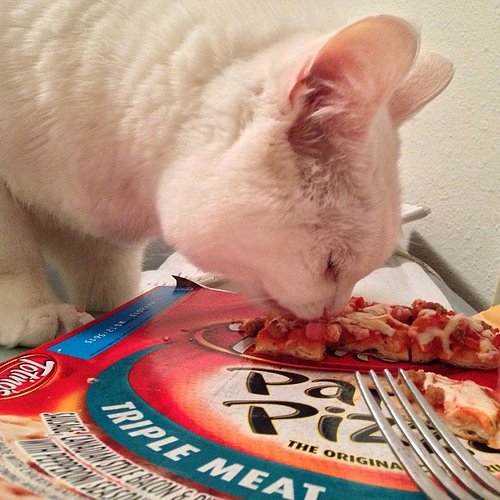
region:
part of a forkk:
[401, 400, 441, 447]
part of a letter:
[233, 398, 267, 450]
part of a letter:
[173, 425, 203, 471]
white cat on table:
[0, 0, 456, 347]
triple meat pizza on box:
[240, 297, 499, 450]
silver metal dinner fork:
[353, 364, 498, 499]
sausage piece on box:
[240, 315, 263, 335]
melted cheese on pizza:
[353, 305, 391, 336]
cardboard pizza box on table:
[0, 276, 497, 497]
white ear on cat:
[300, 12, 420, 126]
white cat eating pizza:
[1, 1, 454, 347]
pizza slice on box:
[238, 296, 498, 367]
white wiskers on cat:
[199, 285, 323, 317]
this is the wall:
[451, 203, 467, 225]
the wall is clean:
[439, 195, 475, 236]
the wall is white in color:
[440, 189, 481, 231]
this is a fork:
[344, 363, 490, 499]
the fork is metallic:
[352, 362, 494, 495]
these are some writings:
[231, 355, 350, 455]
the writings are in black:
[236, 363, 365, 455]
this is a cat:
[9, 11, 437, 332]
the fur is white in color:
[238, 180, 263, 203]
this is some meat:
[355, 301, 447, 336]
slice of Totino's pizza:
[241, 297, 498, 368]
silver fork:
[351, 370, 497, 496]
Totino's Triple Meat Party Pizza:
[0, 274, 498, 498]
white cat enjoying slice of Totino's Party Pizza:
[2, 3, 496, 496]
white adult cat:
[0, 1, 455, 347]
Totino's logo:
[0, 347, 60, 414]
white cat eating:
[0, 3, 453, 354]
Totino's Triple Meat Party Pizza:
[239, 288, 497, 364]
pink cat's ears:
[283, 12, 455, 146]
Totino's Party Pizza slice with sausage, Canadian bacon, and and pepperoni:
[240, 295, 498, 367]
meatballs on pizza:
[407, 293, 499, 336]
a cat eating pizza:
[0, 5, 482, 383]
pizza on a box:
[248, 285, 498, 451]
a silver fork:
[342, 356, 497, 496]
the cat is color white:
[2, 0, 463, 355]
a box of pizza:
[12, 272, 482, 497]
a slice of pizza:
[238, 286, 498, 372]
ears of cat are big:
[291, 10, 459, 151]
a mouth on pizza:
[242, 271, 378, 366]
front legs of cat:
[6, 213, 151, 370]